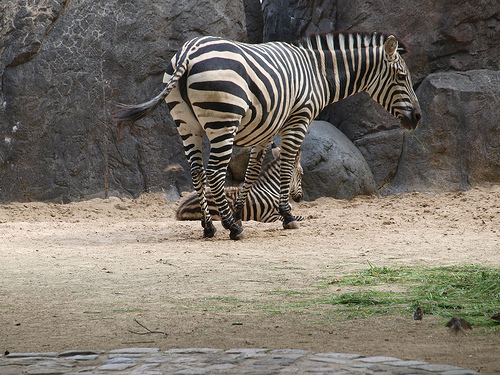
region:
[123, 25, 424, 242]
an adult zebra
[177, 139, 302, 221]
a baby zebra lying on the ground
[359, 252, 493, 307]
a patch of green grass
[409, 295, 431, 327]
a tiny black bird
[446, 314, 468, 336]
a tiny black bird perched on the ground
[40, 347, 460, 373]
gray stones buried in the sand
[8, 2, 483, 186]
a large gray rock wall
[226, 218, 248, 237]
a sturdy black hoof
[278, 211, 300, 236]
a sturdy black hoof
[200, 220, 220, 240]
a sturdy black hoof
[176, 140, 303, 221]
Baby zebra laying down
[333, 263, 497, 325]
Grass feed for zebras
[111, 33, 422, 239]
Adult zebra watching over baby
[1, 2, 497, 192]
Rock landscaping in zebra enclosure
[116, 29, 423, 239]
Zebra swinging tail as it walks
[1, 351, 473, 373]
Flat stones in zebra enclosure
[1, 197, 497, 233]
Soft dirt for baby zebra to lay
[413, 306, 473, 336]
Small birds in zebra enclosure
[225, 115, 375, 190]
Small boulder in zebra enclosure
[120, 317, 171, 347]
Small sticks in zebra enclosure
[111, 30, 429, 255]
Zebra standing up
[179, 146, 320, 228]
Small zebra laying down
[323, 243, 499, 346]
Small area of grass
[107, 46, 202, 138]
Black and white striped zebra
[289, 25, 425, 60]
Black and white mane on zebra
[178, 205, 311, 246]
Black and white hooves on zebra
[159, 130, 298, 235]
Baby zebra looking at rocks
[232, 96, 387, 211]
Large grey rock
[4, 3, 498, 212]
Grey and white rock wall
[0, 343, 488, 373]
Grey stone path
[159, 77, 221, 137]
this is the behind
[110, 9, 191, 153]
this is a tail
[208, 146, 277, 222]
these are some legs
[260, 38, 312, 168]
this is a zebra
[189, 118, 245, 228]
this is a hoof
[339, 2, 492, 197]
this is a head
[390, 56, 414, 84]
this is an eye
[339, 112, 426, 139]
this is a mouth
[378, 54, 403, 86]
this is a face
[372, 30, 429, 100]
the eye is black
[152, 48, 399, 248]
two zebras in the area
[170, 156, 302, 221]
baby zebra sitting on the ground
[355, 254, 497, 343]
patch of grass on the side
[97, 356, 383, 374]
circle of brick in the area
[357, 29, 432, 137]
zebra looking to his left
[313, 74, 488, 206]
big rock in the back of animals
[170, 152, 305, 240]
zebra has four legs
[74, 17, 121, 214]
twig sticking out of ground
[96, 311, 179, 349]
twigs on the ground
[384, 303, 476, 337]
leaves near the grass